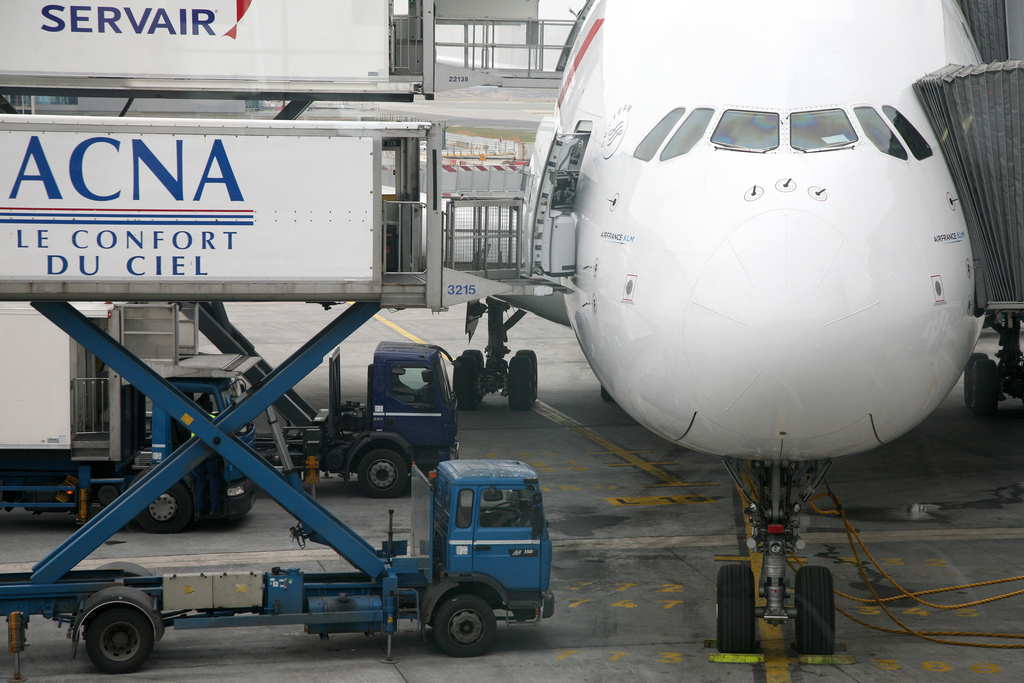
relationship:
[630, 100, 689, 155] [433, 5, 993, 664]
window on a plane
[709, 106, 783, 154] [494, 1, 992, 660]
window built into plane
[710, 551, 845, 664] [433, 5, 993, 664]
wheels on plane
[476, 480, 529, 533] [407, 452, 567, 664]
window on truck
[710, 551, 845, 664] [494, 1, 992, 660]
wheels on plane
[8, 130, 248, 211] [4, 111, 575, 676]
acna on truck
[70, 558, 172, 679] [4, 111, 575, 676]
wheels on truck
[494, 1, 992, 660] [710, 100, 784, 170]
plane has window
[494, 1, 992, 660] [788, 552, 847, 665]
plane has wheel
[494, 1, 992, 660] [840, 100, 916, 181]
plane has window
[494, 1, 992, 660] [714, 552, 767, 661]
plane has wheel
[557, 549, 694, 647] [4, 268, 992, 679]
water on cement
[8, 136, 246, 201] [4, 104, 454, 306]
acna on trailer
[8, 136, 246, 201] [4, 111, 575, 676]
acna on truck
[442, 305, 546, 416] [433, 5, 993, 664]
wheels on plane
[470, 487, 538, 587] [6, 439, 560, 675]
door on truck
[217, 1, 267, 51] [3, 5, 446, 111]
part on truck